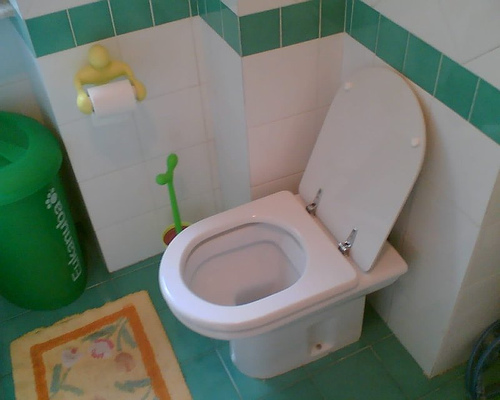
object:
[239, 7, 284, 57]
ceramic tile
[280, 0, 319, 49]
ceramic tile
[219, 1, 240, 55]
ceramic tile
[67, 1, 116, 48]
ceramic tile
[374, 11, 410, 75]
ceramic tile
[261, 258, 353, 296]
toilet seat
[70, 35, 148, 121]
holder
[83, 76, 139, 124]
toilet paper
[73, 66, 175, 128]
toilet paper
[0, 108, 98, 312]
container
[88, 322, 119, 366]
flower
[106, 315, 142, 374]
flower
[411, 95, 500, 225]
tile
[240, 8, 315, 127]
wall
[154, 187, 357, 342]
seat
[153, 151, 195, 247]
toilet plunger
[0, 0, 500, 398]
bathroom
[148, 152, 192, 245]
plunger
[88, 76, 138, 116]
toilet paper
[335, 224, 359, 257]
hardware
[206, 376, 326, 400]
floor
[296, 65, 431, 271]
seat cover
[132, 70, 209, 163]
tile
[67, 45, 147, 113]
toilet-paper holder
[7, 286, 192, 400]
rug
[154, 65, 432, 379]
toilet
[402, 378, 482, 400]
floor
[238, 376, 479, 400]
ground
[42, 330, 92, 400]
flowers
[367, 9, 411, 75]
green tiles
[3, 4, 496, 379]
walls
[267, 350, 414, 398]
floor tile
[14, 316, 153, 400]
floor